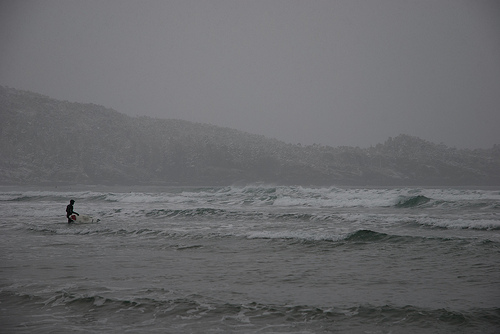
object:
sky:
[0, 0, 500, 150]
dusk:
[376, 120, 454, 133]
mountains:
[0, 84, 497, 188]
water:
[0, 181, 500, 334]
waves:
[0, 187, 500, 324]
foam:
[132, 195, 189, 204]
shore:
[0, 183, 191, 193]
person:
[66, 199, 80, 223]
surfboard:
[68, 217, 100, 225]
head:
[70, 199, 75, 205]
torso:
[66, 204, 73, 214]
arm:
[72, 206, 78, 215]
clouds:
[0, 0, 500, 151]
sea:
[317, 211, 411, 279]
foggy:
[0, 0, 499, 294]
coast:
[0, 170, 500, 191]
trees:
[381, 135, 445, 162]